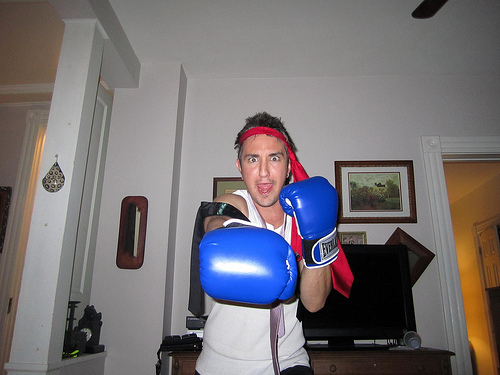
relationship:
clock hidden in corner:
[78, 303, 105, 355] [0, 21, 171, 372]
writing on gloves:
[303, 232, 358, 267] [177, 173, 365, 310]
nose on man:
[259, 159, 268, 179] [193, 110, 334, 374]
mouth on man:
[252, 175, 278, 199] [193, 110, 334, 374]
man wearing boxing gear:
[182, 106, 347, 373] [196, 218, 301, 306]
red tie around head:
[236, 126, 354, 299] [235, 113, 297, 205]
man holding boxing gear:
[193, 110, 334, 374] [196, 218, 301, 306]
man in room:
[193, 110, 334, 374] [1, 2, 498, 370]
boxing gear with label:
[280, 176, 341, 270] [318, 226, 338, 262]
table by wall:
[167, 345, 457, 373] [169, 74, 499, 374]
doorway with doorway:
[421, 131, 499, 373] [421, 131, 499, 373]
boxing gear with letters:
[280, 176, 341, 270] [316, 232, 343, 264]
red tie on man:
[227, 117, 354, 295] [197, 111, 357, 368]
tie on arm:
[185, 198, 244, 320] [197, 185, 298, 312]